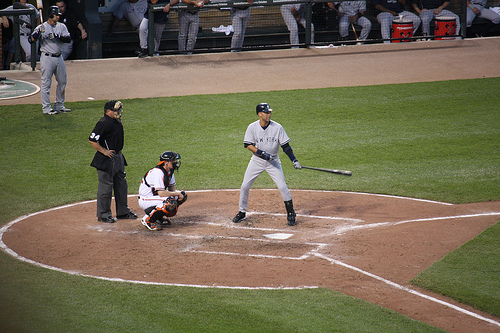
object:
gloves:
[260, 151, 276, 161]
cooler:
[392, 18, 414, 43]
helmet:
[47, 6, 63, 17]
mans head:
[48, 6, 59, 22]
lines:
[314, 251, 500, 326]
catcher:
[138, 150, 188, 231]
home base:
[260, 227, 298, 241]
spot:
[87, 97, 95, 100]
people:
[461, 0, 500, 31]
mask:
[113, 101, 124, 119]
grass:
[0, 79, 497, 329]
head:
[256, 102, 271, 122]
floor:
[0, 37, 500, 333]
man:
[87, 100, 139, 223]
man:
[26, 6, 72, 114]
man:
[137, 2, 172, 59]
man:
[163, 0, 204, 54]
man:
[338, 0, 372, 45]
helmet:
[255, 102, 273, 114]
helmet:
[158, 151, 182, 166]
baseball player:
[231, 102, 301, 225]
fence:
[153, 2, 497, 53]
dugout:
[1, 0, 500, 61]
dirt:
[2, 188, 499, 333]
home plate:
[263, 229, 295, 241]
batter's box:
[224, 206, 368, 236]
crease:
[253, 157, 277, 167]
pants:
[239, 153, 293, 213]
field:
[0, 37, 500, 333]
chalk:
[2, 187, 500, 330]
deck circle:
[0, 76, 41, 100]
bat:
[301, 166, 353, 176]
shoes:
[229, 209, 298, 227]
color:
[392, 192, 454, 206]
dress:
[239, 119, 298, 212]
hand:
[259, 150, 274, 161]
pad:
[163, 197, 178, 217]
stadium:
[1, 2, 498, 330]